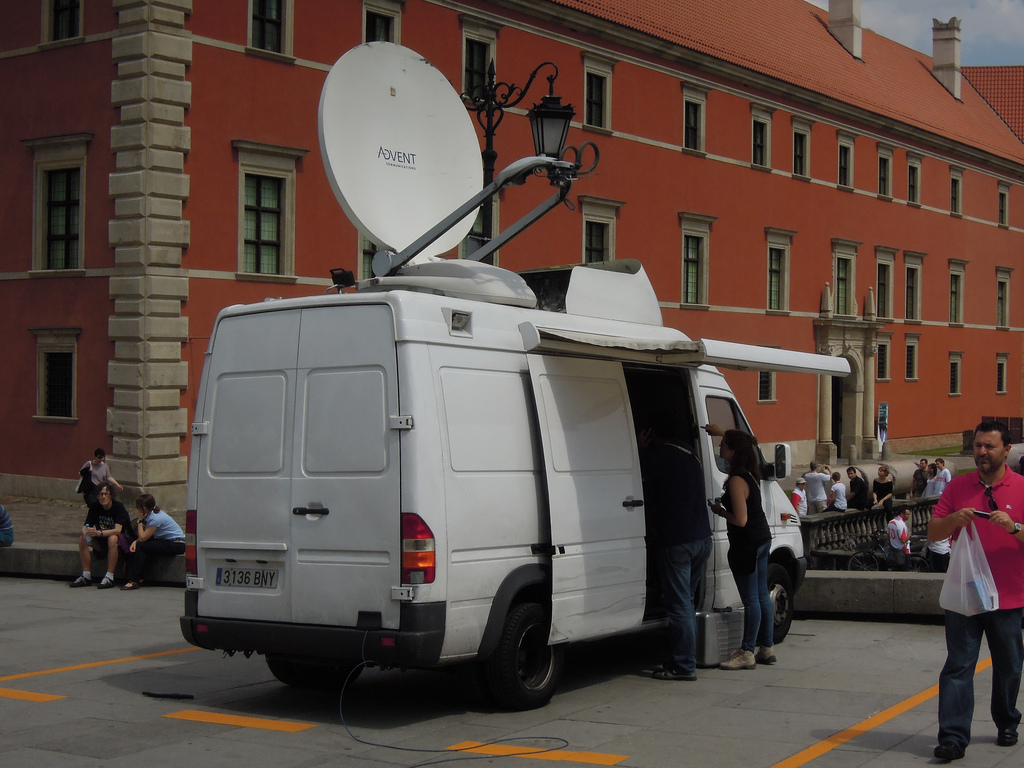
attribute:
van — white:
[196, 280, 844, 688]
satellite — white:
[318, 31, 512, 267]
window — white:
[582, 74, 617, 139]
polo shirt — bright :
[942, 478, 1020, 600]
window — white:
[714, 64, 771, 176]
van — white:
[174, 303, 801, 664]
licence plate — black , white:
[209, 554, 286, 589]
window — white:
[685, 232, 708, 300]